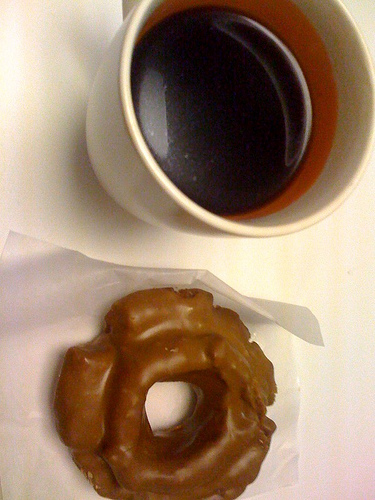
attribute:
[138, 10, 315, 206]
liquid — dark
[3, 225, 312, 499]
wax paper — white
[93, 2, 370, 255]
cup — white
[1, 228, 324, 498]
paper — white, wax paper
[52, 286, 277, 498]
donut — whole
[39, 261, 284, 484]
item — chocolate, food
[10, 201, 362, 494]
surface — white